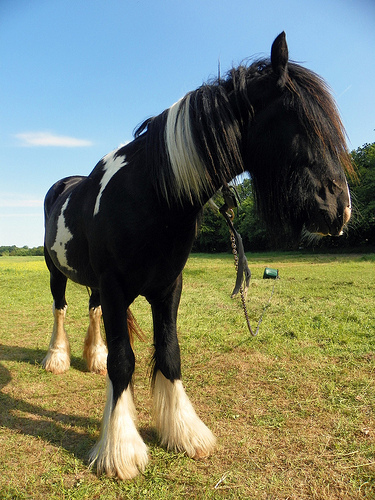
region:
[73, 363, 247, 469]
white feet on horse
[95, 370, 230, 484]
white fur on horse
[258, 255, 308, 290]
green bucket behind horse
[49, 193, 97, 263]
white spot on horse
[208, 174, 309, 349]
black rope on horse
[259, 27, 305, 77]
black ear on horse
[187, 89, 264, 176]
black mane on horse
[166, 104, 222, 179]
white mane on horse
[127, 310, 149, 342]
black tail on horse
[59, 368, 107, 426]
dead grass under horse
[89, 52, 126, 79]
blue sky above the ground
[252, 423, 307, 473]
green grass on the ground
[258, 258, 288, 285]
object on the ground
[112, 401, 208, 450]
feet of the horse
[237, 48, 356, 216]
head of the horse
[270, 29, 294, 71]
ear of the horse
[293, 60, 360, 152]
hair on the horse's head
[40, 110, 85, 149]
white cloud in the sky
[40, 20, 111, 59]
blue sky behind the cloud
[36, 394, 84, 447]
shadow on the ground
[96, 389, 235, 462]
the hooves are white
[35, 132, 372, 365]
the horse is black and white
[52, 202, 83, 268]
the patch is white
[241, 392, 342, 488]
the ground has brown grass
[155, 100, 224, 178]
the hair is white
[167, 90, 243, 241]
chain is on the horse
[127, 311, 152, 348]
the tail is brown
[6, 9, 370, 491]
the scene is outdoors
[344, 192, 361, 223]
the nose patch is white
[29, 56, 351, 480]
the horse is tall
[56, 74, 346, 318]
a unique looking horse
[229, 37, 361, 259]
a horses head with long hair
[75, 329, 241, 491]
the horses legs are white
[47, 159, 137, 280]
this horse has white spots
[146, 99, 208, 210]
the horses main is white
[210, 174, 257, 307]
some kind of chain around the horses neck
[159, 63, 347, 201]
this horses main goes downward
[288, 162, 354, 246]
the horse's nose is broad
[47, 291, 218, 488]
this horse has four white legs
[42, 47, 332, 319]
this is a unique looking horse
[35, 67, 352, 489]
Clydesdale horse standing in field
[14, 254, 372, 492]
Trimmed green grass on field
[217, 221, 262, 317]
Metal chain hanging from horse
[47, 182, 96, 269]
White spots on horse's back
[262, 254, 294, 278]
Green feed bucket on field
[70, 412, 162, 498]
Long white hair covering hoof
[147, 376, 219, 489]
Long white hair covering hoof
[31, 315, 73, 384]
Long white hair covering hoof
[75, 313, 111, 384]
Long white hair covering hoof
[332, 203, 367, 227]
Pink nose on black horse